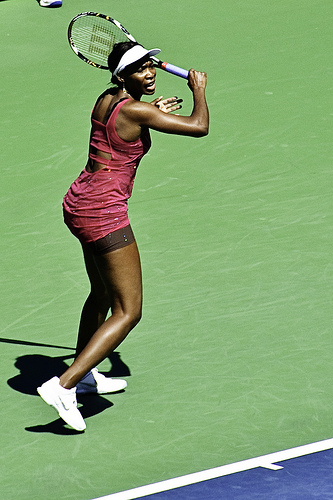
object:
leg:
[75, 245, 129, 397]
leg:
[36, 212, 144, 434]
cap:
[111, 44, 162, 81]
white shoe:
[75, 366, 128, 396]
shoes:
[34, 375, 90, 436]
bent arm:
[120, 88, 211, 140]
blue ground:
[127, 444, 333, 500]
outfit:
[60, 85, 154, 260]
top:
[61, 84, 153, 245]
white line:
[87, 434, 333, 500]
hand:
[186, 66, 209, 93]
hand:
[149, 94, 184, 117]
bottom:
[80, 221, 136, 259]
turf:
[0, 0, 333, 500]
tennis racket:
[65, 8, 191, 82]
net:
[70, 14, 131, 69]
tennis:
[6, 5, 237, 465]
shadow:
[0, 320, 133, 437]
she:
[35, 38, 212, 436]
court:
[0, 1, 333, 500]